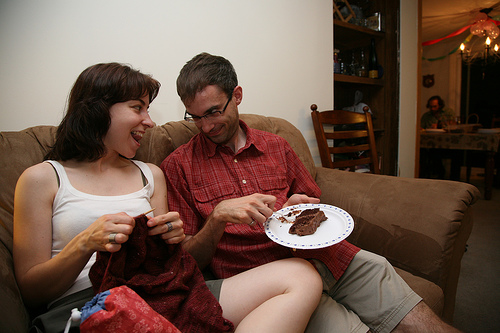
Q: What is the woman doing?
A: Crocheting.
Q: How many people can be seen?
A: Two.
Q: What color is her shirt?
A: White.